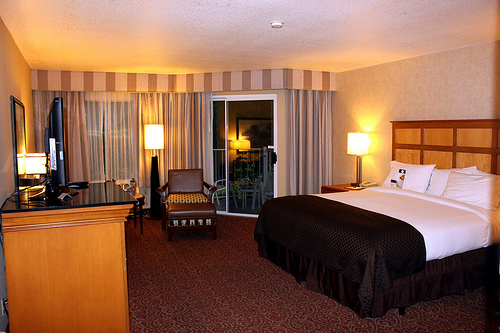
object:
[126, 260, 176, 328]
carpet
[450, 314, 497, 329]
floor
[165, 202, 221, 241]
rest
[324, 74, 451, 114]
wall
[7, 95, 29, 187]
image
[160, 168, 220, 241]
chair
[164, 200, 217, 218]
ottoman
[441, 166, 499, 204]
pillow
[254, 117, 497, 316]
bed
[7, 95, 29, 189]
television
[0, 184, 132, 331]
dresser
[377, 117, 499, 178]
headboard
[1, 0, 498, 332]
room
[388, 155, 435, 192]
pillow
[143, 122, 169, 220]
lamp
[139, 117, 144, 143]
shade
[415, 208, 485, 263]
white sheets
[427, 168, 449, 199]
pillowcases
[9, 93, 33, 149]
picture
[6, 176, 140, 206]
surface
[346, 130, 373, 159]
white lampshade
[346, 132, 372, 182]
lamp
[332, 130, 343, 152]
shade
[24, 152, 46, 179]
lamp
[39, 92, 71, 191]
tv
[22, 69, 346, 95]
striped valance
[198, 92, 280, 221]
door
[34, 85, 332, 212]
brown drapes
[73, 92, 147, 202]
window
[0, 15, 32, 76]
wall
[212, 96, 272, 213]
patio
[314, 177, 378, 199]
desk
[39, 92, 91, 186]
drape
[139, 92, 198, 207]
drape